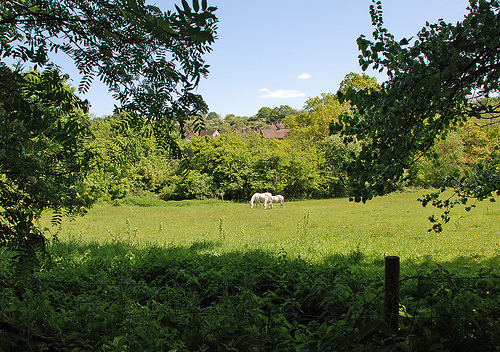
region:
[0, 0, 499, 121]
The sky is clear.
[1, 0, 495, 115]
The sky is blue.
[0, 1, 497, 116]
A few clouds are in the sky.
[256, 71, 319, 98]
The clouds are white.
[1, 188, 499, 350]
The grass is green.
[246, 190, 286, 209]
The horses are grazing.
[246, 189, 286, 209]
The horses are white.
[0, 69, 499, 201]
The trees are green.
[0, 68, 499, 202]
The trees have leaves.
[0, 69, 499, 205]
Trees are in the background.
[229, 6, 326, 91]
this is the sky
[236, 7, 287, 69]
the sky is blue in color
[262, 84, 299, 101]
this is the clouds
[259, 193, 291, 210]
this is a horse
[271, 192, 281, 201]
the horse is white in color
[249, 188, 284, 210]
the are two horses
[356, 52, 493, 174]
this is a tree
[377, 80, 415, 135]
the leaves are green in color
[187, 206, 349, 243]
this is a grass area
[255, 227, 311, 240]
the grass is green in color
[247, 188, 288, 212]
Two white horse in the grass.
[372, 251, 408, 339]
Wooden fence posts in forefront.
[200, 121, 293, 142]
House roofs in background.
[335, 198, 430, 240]
Green grass in pasture.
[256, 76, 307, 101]
White cloud in the sky.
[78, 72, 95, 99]
Long stemmed green leaf.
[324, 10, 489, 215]
Tree branches hanging from tree.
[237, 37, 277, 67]
Blue sky in the background.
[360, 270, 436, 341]
Broken fence wire beside post.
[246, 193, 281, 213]
Horses eating grass.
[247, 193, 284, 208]
Two horses on the grass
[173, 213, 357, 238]
A field of green grass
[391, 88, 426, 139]
Green leaves on the tree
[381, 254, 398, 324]
A wooden post above the grass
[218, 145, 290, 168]
Green trees behind the horses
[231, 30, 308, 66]
Blue sky above the horses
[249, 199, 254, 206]
The head of a horse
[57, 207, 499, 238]
A green field around the horses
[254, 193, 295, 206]
The horses are white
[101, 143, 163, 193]
Trees to the left of the horses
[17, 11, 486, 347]
picture taken outdoors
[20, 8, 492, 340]
picture taken during the day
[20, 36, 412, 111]
the sky has a few clouds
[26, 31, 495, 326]
a view of a pasture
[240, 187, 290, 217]
two horses on the grass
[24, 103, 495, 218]
trees are in the front of the picture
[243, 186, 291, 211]
the horses are white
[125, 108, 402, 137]
tall trees in the background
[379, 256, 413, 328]
a wood post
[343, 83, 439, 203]
the tree has leaves